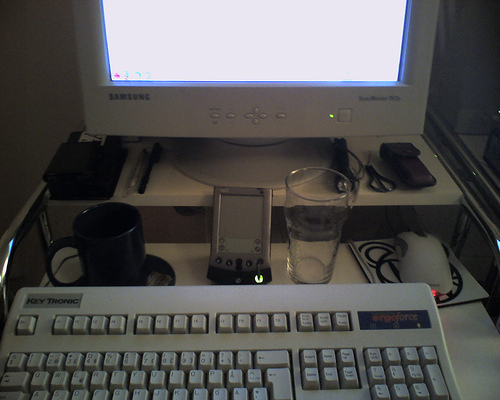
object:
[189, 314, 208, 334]
key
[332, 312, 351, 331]
key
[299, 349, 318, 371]
key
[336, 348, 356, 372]
key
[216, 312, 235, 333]
key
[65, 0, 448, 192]
monitor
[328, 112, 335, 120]
power light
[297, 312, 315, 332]
key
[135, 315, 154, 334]
key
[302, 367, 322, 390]
key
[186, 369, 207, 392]
key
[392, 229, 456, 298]
mouse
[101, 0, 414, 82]
screen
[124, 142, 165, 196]
two pens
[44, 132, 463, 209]
desk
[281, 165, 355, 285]
glass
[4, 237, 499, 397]
desk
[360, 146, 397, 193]
scissors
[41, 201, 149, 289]
coffee mug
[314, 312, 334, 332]
key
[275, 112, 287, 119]
buttons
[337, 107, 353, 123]
button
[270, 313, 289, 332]
key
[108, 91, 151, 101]
samsung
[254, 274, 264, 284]
green light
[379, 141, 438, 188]
leatherman case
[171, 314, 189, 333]
key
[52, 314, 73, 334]
key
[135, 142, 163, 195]
pen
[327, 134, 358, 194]
pen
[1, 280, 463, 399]
keypad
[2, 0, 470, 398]
laptop